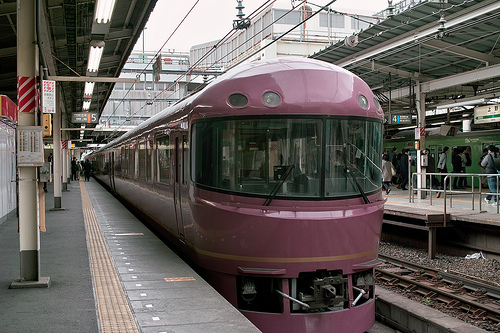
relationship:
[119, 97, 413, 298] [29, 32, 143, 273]
train at depot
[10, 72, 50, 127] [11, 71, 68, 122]
red and white striped sign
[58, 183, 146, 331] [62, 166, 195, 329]
yellow lines on sidewalk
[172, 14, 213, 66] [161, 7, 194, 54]
gray day in sky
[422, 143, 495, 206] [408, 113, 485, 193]
windsjile of train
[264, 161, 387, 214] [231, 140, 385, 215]
wipers on front glass window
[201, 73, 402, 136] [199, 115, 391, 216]
lights over front windshield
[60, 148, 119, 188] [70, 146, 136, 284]
people waiting on platform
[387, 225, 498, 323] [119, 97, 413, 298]
tracks next to purple train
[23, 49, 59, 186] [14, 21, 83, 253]
postings on platform pillars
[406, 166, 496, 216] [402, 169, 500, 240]
safety rails on train platform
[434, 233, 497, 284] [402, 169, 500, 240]
trash near platform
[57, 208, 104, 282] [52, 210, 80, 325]
part of floor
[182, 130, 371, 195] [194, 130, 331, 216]
part of a window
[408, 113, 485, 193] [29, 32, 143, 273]
train at depot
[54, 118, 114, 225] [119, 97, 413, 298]
people standing next to train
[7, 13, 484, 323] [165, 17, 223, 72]
picture taken during day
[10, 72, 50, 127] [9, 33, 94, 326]
red and white sign on post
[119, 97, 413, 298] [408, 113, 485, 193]
commuter green train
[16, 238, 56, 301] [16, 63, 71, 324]
base of metal pillar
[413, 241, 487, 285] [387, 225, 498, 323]
gravel on train track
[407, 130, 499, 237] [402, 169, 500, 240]
metal hand railing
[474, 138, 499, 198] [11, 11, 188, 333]
person at train station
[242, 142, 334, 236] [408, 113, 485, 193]
windshield wiper on train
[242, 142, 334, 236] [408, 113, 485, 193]
windshield of train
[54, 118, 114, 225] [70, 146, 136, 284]
people standing on platform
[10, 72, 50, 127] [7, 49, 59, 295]
red and white safety sign on pole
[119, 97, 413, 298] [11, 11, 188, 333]
train stopped at station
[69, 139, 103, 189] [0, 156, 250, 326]
people on platform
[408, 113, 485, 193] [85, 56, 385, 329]
people getting getting on train